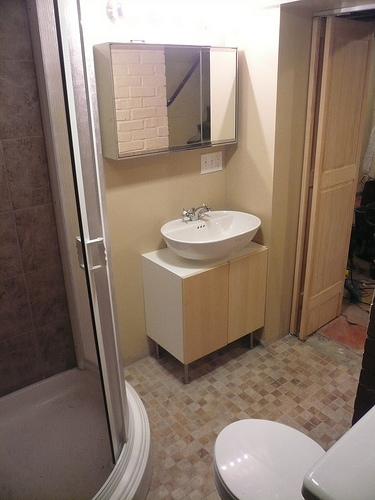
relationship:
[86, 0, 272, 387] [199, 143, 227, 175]
wall has outlets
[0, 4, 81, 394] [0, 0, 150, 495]
tiles are on a shower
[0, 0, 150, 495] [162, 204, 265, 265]
shower next to sink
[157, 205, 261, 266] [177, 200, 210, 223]
sink has faucet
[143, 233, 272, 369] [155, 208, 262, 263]
cabinet under sink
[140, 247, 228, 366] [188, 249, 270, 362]
cabinet has doors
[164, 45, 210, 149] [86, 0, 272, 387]
mirror on wall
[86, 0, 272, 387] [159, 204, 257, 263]
wall above sink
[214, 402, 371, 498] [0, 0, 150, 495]
toilet in front of shower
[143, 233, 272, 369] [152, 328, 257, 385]
cabinet has legs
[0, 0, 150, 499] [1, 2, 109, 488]
shower with a door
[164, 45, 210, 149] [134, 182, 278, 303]
mirror above sink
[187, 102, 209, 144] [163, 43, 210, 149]
staircase in mirror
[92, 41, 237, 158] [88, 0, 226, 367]
medicine cabinet on wall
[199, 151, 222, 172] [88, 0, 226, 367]
light switch on wall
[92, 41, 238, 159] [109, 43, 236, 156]
medicine cabinet with mirrors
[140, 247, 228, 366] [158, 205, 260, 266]
cabinet underneath sink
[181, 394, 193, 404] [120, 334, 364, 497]
tile on floor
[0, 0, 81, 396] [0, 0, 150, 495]
wall in shower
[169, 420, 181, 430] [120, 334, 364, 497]
tile on floor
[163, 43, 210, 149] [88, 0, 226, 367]
mirror on wall